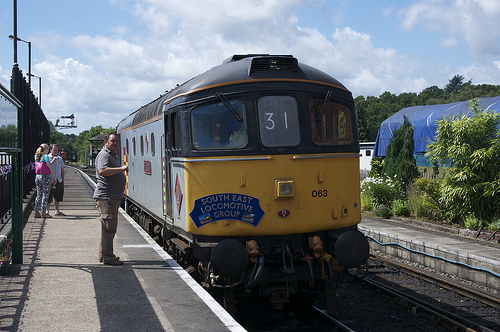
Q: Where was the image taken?
A: It was taken at the sidewalk.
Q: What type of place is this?
A: It is a sidewalk.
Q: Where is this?
A: This is at the sidewalk.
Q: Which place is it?
A: It is a sidewalk.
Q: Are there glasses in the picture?
A: No, there are no glasses.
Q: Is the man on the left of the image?
A: Yes, the man is on the left of the image.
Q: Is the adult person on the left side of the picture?
A: Yes, the man is on the left of the image.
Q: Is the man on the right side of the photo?
A: No, the man is on the left of the image.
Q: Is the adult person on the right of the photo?
A: No, the man is on the left of the image.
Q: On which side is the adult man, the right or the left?
A: The man is on the left of the image.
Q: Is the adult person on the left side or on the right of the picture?
A: The man is on the left of the image.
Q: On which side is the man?
A: The man is on the left of the image.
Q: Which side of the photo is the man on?
A: The man is on the left of the image.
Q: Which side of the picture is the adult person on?
A: The man is on the left of the image.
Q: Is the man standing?
A: Yes, the man is standing.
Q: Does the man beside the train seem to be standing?
A: Yes, the man is standing.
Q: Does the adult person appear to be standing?
A: Yes, the man is standing.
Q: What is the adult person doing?
A: The man is standing.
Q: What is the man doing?
A: The man is standing.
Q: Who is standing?
A: The man is standing.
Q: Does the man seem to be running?
A: No, the man is standing.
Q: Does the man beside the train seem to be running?
A: No, the man is standing.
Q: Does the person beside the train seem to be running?
A: No, the man is standing.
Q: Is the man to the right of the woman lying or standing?
A: The man is standing.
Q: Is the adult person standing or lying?
A: The man is standing.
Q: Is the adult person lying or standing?
A: The man is standing.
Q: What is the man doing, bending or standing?
A: The man is standing.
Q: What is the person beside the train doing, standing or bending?
A: The man is standing.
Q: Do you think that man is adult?
A: Yes, the man is adult.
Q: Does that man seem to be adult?
A: Yes, the man is adult.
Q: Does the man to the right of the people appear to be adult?
A: Yes, the man is adult.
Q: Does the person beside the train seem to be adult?
A: Yes, the man is adult.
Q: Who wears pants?
A: The man wears pants.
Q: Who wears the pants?
A: The man wears pants.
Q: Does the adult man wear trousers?
A: Yes, the man wears trousers.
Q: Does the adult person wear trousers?
A: Yes, the man wears trousers.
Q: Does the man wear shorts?
A: No, the man wears trousers.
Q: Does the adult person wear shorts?
A: No, the man wears trousers.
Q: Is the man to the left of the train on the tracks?
A: Yes, the man is to the left of the train.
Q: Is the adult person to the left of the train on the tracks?
A: Yes, the man is to the left of the train.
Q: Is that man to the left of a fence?
A: No, the man is to the left of the train.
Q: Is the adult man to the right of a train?
A: No, the man is to the left of a train.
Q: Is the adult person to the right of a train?
A: No, the man is to the left of a train.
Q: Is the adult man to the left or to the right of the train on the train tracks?
A: The man is to the left of the train.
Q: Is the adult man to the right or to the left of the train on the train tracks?
A: The man is to the left of the train.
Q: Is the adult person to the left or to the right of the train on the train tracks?
A: The man is to the left of the train.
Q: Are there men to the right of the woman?
A: Yes, there is a man to the right of the woman.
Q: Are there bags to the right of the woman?
A: No, there is a man to the right of the woman.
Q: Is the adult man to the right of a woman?
A: Yes, the man is to the right of a woman.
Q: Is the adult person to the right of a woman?
A: Yes, the man is to the right of a woman.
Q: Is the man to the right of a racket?
A: No, the man is to the right of a woman.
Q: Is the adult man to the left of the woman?
A: No, the man is to the right of the woman.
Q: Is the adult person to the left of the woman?
A: No, the man is to the right of the woman.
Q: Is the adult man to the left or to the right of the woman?
A: The man is to the right of the woman.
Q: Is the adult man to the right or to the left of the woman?
A: The man is to the right of the woman.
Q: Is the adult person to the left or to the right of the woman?
A: The man is to the right of the woman.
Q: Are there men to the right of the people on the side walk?
A: Yes, there is a man to the right of the people.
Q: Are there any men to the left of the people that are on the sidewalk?
A: No, the man is to the right of the people.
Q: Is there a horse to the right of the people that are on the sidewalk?
A: No, there is a man to the right of the people.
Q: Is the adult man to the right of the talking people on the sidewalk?
A: Yes, the man is to the right of the people.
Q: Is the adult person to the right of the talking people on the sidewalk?
A: Yes, the man is to the right of the people.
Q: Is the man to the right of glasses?
A: No, the man is to the right of the people.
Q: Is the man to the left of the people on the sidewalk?
A: No, the man is to the right of the people.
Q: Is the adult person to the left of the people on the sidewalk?
A: No, the man is to the right of the people.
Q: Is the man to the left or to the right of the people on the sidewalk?
A: The man is to the right of the people.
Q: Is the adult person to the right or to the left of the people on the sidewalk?
A: The man is to the right of the people.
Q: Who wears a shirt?
A: The man wears a shirt.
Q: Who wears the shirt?
A: The man wears a shirt.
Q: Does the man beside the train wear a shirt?
A: Yes, the man wears a shirt.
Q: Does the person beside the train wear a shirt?
A: Yes, the man wears a shirt.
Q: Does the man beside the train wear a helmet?
A: No, the man wears a shirt.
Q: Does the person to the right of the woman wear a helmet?
A: No, the man wears a shirt.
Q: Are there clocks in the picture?
A: No, there are no clocks.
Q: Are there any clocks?
A: No, there are no clocks.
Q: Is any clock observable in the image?
A: No, there are no clocks.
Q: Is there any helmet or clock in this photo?
A: No, there are no clocks or helmets.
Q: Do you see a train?
A: Yes, there is a train.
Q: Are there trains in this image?
A: Yes, there is a train.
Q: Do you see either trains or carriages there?
A: Yes, there is a train.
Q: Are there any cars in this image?
A: No, there are no cars.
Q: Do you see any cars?
A: No, there are no cars.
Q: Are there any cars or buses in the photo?
A: No, there are no cars or buses.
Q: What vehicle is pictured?
A: The vehicle is a train.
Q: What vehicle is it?
A: The vehicle is a train.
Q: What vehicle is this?
A: This is a train.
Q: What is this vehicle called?
A: This is a train.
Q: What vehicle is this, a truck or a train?
A: This is a train.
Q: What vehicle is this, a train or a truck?
A: This is a train.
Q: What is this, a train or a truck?
A: This is a train.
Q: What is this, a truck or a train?
A: This is a train.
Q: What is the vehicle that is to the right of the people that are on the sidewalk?
A: The vehicle is a train.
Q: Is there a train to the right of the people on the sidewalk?
A: Yes, there is a train to the right of the people.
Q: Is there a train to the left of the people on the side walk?
A: No, the train is to the right of the people.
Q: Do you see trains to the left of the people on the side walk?
A: No, the train is to the right of the people.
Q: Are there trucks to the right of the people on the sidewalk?
A: No, there is a train to the right of the people.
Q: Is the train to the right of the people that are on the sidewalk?
A: Yes, the train is to the right of the people.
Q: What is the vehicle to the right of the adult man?
A: The vehicle is a train.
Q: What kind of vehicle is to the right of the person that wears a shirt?
A: The vehicle is a train.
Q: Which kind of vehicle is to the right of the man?
A: The vehicle is a train.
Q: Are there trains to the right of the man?
A: Yes, there is a train to the right of the man.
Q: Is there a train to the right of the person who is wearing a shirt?
A: Yes, there is a train to the right of the man.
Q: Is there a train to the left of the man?
A: No, the train is to the right of the man.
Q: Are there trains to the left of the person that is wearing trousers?
A: No, the train is to the right of the man.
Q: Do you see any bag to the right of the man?
A: No, there is a train to the right of the man.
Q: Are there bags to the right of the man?
A: No, there is a train to the right of the man.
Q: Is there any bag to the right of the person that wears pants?
A: No, there is a train to the right of the man.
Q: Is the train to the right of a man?
A: Yes, the train is to the right of a man.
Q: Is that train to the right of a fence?
A: No, the train is to the right of a man.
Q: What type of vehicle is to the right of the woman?
A: The vehicle is a train.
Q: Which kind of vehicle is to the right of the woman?
A: The vehicle is a train.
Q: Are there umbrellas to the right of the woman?
A: No, there is a train to the right of the woman.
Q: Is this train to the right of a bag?
A: No, the train is to the right of a woman.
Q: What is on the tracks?
A: The train is on the tracks.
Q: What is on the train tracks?
A: The train is on the tracks.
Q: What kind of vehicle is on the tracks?
A: The vehicle is a train.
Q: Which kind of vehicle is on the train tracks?
A: The vehicle is a train.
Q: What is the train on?
A: The train is on the railroad tracks.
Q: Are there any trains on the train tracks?
A: Yes, there is a train on the train tracks.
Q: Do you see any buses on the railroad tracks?
A: No, there is a train on the railroad tracks.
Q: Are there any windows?
A: Yes, there is a window.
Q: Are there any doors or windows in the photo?
A: Yes, there is a window.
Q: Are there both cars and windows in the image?
A: No, there is a window but no cars.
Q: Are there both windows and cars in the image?
A: No, there is a window but no cars.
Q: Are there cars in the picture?
A: No, there are no cars.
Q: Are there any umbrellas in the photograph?
A: No, there are no umbrellas.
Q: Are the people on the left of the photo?
A: Yes, the people are on the left of the image.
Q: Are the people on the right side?
A: No, the people are on the left of the image.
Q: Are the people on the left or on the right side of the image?
A: The people are on the left of the image.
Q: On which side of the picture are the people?
A: The people are on the left of the image.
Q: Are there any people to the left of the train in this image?
A: Yes, there are people to the left of the train.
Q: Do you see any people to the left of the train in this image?
A: Yes, there are people to the left of the train.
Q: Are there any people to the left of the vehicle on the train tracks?
A: Yes, there are people to the left of the train.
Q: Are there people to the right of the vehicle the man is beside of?
A: No, the people are to the left of the train.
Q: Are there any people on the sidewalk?
A: Yes, there are people on the sidewalk.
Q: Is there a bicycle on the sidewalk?
A: No, there are people on the sidewalk.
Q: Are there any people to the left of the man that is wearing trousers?
A: Yes, there are people to the left of the man.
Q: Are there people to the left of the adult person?
A: Yes, there are people to the left of the man.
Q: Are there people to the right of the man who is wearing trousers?
A: No, the people are to the left of the man.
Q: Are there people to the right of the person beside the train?
A: No, the people are to the left of the man.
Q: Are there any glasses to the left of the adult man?
A: No, there are people to the left of the man.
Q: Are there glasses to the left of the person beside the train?
A: No, there are people to the left of the man.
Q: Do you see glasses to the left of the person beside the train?
A: No, there are people to the left of the man.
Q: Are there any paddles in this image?
A: No, there are no paddles.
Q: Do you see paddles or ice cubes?
A: No, there are no paddles or ice cubes.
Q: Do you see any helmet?
A: No, there are no helmets.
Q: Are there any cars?
A: No, there are no cars.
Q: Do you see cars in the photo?
A: No, there are no cars.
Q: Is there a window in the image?
A: Yes, there is a window.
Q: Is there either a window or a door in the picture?
A: Yes, there is a window.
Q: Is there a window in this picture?
A: Yes, there is a window.